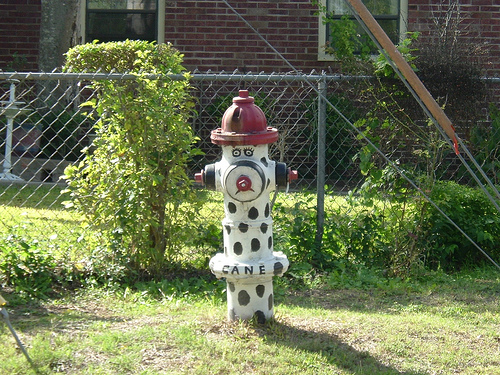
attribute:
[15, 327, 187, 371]
grass — on the ground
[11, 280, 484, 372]
grass — brown, dried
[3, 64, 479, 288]
fence — short, metal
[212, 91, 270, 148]
top — red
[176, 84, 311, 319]
pipe — water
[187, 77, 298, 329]
hydrant — polkadotted, white, black, fire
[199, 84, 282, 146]
top — red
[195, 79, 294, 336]
hydrant — fire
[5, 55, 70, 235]
fence — metal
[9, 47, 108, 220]
fence — short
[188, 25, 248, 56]
wall — brick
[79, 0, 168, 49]
window — closed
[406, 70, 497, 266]
wires — thick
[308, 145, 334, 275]
pole — thin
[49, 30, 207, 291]
bush — green, small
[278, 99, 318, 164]
wire fence — wire 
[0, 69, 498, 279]
fence — metal, chain link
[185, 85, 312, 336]
hydrant — fire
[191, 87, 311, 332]
pipe — water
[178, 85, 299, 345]
pipe — water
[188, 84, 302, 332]
pipe — water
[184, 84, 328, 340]
hydrant — fire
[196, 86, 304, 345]
hydrant — fire, white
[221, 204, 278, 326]
spots — black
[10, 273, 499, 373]
grass — green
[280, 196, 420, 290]
plants — green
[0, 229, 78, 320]
plants — green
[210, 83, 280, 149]
top — red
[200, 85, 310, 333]
hydrant — fire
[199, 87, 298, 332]
hydrant — fire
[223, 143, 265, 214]
face — frowning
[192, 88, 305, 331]
hydrant — fire